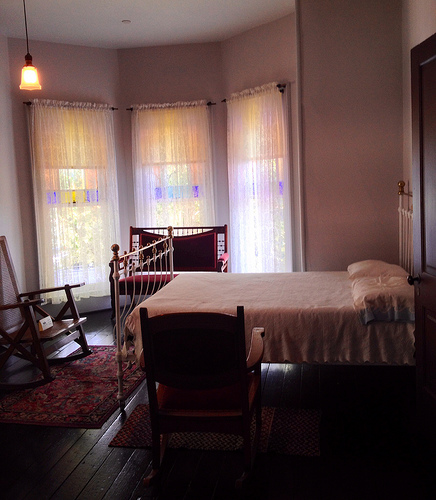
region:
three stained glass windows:
[43, 139, 284, 210]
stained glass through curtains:
[49, 155, 98, 211]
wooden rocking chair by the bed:
[135, 284, 284, 498]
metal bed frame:
[99, 228, 183, 335]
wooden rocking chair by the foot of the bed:
[5, 250, 105, 399]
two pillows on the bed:
[340, 260, 416, 325]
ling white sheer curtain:
[218, 91, 292, 295]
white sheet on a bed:
[206, 265, 323, 332]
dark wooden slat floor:
[38, 437, 125, 483]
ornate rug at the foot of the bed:
[59, 362, 108, 421]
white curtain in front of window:
[221, 79, 297, 279]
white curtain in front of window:
[125, 94, 229, 239]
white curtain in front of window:
[29, 97, 123, 308]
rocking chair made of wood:
[0, 228, 94, 389]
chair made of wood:
[129, 291, 281, 490]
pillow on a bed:
[344, 272, 418, 324]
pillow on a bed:
[340, 256, 409, 282]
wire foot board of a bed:
[103, 221, 183, 433]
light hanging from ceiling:
[11, 0, 48, 95]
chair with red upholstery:
[100, 220, 240, 321]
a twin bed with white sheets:
[97, 204, 432, 375]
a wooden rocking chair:
[118, 297, 283, 495]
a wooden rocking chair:
[0, 237, 110, 387]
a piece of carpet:
[0, 331, 171, 437]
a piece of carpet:
[94, 383, 343, 463]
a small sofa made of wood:
[89, 224, 233, 328]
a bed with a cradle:
[97, 212, 435, 408]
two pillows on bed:
[341, 253, 420, 325]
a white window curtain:
[22, 84, 142, 311]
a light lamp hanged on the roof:
[11, 1, 57, 102]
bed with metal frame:
[100, 172, 427, 427]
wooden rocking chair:
[0, 231, 99, 395]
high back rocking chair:
[1, 224, 100, 394]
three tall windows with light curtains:
[16, 84, 305, 309]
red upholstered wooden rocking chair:
[128, 301, 279, 488]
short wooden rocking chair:
[122, 297, 272, 498]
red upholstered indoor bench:
[98, 216, 244, 325]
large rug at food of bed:
[2, 323, 148, 428]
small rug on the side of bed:
[109, 398, 330, 460]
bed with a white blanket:
[102, 170, 426, 440]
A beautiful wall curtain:
[217, 87, 296, 262]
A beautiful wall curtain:
[34, 185, 107, 288]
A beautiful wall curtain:
[133, 189, 212, 226]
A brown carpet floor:
[16, 343, 114, 432]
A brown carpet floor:
[122, 400, 326, 445]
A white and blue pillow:
[352, 277, 420, 329]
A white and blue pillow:
[343, 258, 394, 274]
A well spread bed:
[152, 250, 418, 349]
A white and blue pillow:
[28, 429, 112, 486]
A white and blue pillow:
[160, 455, 277, 498]